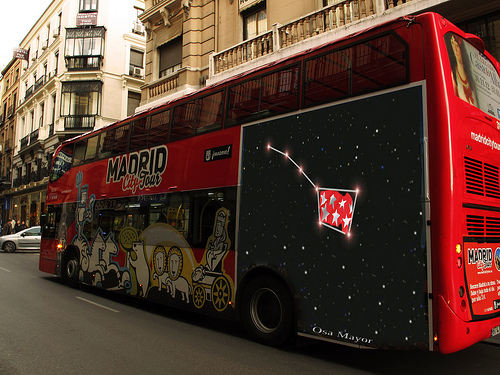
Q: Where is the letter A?
A: On the bus.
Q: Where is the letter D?
A: On the bus.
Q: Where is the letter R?
A: On the bus.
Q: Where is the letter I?
A: On the bus.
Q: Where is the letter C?
A: On the bus.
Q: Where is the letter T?
A: On the bus.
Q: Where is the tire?
A: On the bus.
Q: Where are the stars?
A: On the bus.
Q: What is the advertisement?
A: Black.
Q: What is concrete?
A: Street.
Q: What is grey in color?
A: Street.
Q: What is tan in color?
A: Building.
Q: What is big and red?
A: Bus.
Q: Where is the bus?
A: On the street.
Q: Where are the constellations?
A: On the side of the bus.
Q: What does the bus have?
A: Side.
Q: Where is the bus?
A: Madrid.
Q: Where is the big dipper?
A: On the side of the bus.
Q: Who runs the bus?
A: Madrid city tour.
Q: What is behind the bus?
A: Some tan buildings.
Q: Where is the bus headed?
A: Away from the viewer.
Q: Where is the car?
A: Ahead of the bus.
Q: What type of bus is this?
A: A red double decker.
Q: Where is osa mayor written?
A: Under the big dipper.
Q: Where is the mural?
A: On the side of the bus.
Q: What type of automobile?
A: Bus.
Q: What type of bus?
A: Double decker.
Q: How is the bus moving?
A: On wheels.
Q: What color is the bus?
A: Red.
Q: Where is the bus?
A: On the street.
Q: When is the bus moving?
A: During the day.